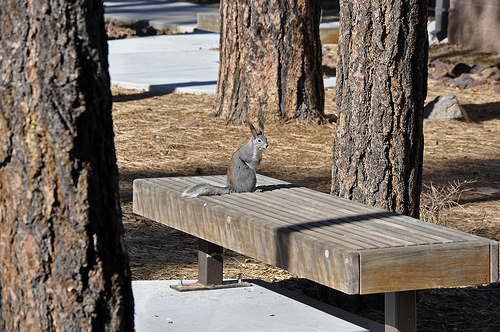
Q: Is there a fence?
A: No, there are no fences.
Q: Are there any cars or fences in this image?
A: No, there are no fences or cars.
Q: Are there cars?
A: No, there are no cars.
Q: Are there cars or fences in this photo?
A: No, there are no cars or fences.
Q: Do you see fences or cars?
A: No, there are no cars or fences.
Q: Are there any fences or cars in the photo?
A: No, there are no cars or fences.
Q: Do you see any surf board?
A: No, there are no surfboards.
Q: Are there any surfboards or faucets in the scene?
A: No, there are no surfboards or faucets.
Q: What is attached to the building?
A: The pipe is attached to the building.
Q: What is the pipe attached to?
A: The pipe is attached to the building.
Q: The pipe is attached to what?
A: The pipe is attached to the building.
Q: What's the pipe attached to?
A: The pipe is attached to the building.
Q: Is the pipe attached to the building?
A: Yes, the pipe is attached to the building.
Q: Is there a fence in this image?
A: No, there are no fences.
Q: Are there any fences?
A: No, there are no fences.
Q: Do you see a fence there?
A: No, there are no fences.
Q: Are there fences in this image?
A: No, there are no fences.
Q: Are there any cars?
A: No, there are no cars.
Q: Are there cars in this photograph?
A: No, there are no cars.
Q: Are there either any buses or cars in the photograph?
A: No, there are no cars or buses.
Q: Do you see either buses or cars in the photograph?
A: No, there are no cars or buses.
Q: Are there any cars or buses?
A: No, there are no cars or buses.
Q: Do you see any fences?
A: No, there are no fences.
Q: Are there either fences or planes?
A: No, there are no fences or planes.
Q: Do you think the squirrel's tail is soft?
A: Yes, the tail is soft.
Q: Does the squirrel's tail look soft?
A: Yes, the tail is soft.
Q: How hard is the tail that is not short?
A: The tail is soft.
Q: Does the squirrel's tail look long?
A: Yes, the tail is long.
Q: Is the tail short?
A: No, the tail is long.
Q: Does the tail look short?
A: No, the tail is long.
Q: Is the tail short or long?
A: The tail is long.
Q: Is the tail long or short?
A: The tail is long.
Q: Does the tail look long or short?
A: The tail is long.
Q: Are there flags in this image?
A: No, there are no flags.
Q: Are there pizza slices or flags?
A: No, there are no flags or pizza slices.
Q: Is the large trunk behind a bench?
A: Yes, the trunk is behind a bench.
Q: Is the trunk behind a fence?
A: No, the trunk is behind a bench.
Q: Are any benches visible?
A: Yes, there is a bench.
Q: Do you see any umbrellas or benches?
A: Yes, there is a bench.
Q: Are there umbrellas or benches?
A: Yes, there is a bench.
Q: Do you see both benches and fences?
A: No, there is a bench but no fences.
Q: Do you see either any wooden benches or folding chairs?
A: Yes, there is a wood bench.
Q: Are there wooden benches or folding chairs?
A: Yes, there is a wood bench.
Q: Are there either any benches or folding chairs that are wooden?
A: Yes, the bench is wooden.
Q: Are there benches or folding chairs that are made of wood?
A: Yes, the bench is made of wood.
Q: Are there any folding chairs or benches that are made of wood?
A: Yes, the bench is made of wood.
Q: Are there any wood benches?
A: Yes, there is a wood bench.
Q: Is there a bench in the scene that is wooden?
A: Yes, there is a bench that is wooden.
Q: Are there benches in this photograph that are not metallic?
A: Yes, there is a wooden bench.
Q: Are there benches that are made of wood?
A: Yes, there is a bench that is made of wood.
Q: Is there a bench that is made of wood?
A: Yes, there is a bench that is made of wood.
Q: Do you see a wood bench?
A: Yes, there is a bench that is made of wood.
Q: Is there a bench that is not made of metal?
A: Yes, there is a bench that is made of wood.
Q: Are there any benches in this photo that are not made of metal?
A: Yes, there is a bench that is made of wood.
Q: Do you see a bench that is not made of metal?
A: Yes, there is a bench that is made of wood.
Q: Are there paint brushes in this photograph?
A: No, there are no paint brushes.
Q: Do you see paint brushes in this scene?
A: No, there are no paint brushes.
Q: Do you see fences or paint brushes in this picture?
A: No, there are no paint brushes or fences.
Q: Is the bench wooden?
A: Yes, the bench is wooden.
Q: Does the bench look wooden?
A: Yes, the bench is wooden.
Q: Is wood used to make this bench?
A: Yes, the bench is made of wood.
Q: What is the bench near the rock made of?
A: The bench is made of wood.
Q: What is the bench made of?
A: The bench is made of wood.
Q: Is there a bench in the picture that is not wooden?
A: No, there is a bench but it is wooden.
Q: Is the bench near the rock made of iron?
A: No, the bench is made of wood.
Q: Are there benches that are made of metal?
A: No, there is a bench but it is made of wood.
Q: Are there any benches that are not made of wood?
A: No, there is a bench but it is made of wood.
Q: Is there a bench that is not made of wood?
A: No, there is a bench but it is made of wood.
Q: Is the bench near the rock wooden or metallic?
A: The bench is wooden.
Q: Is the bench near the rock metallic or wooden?
A: The bench is wooden.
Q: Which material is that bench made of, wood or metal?
A: The bench is made of wood.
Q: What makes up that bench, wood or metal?
A: The bench is made of wood.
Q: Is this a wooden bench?
A: Yes, this is a wooden bench.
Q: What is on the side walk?
A: The bench is on the side walk.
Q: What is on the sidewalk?
A: The bench is on the side walk.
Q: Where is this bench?
A: The bench is on the sidewalk.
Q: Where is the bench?
A: The bench is on the sidewalk.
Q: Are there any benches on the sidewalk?
A: Yes, there is a bench on the sidewalk.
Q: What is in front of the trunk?
A: The bench is in front of the trunk.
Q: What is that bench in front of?
A: The bench is in front of the trunk.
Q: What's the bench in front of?
A: The bench is in front of the trunk.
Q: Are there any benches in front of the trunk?
A: Yes, there is a bench in front of the trunk.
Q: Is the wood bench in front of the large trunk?
A: Yes, the bench is in front of the trunk.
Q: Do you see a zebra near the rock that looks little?
A: No, there is a bench near the rock.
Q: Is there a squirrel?
A: Yes, there is a squirrel.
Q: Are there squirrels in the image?
A: Yes, there is a squirrel.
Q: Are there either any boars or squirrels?
A: Yes, there is a squirrel.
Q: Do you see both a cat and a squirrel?
A: No, there is a squirrel but no cats.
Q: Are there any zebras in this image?
A: No, there are no zebras.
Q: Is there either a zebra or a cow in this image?
A: No, there are no zebras or cows.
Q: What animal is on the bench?
A: The squirrel is on the bench.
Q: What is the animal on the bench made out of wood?
A: The animal is a squirrel.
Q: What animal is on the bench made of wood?
A: The animal is a squirrel.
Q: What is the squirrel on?
A: The squirrel is on the bench.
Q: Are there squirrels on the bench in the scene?
A: Yes, there is a squirrel on the bench.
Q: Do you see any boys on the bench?
A: No, there is a squirrel on the bench.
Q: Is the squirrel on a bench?
A: Yes, the squirrel is on a bench.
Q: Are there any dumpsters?
A: No, there are no dumpsters.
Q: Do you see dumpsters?
A: No, there are no dumpsters.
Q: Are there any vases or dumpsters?
A: No, there are no dumpsters or vases.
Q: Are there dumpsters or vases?
A: No, there are no dumpsters or vases.